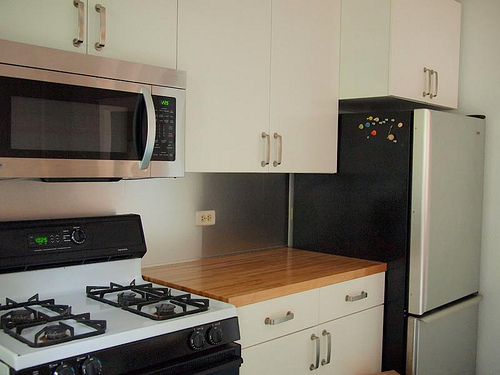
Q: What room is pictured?
A: It is a kitchen.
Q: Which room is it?
A: It is a kitchen.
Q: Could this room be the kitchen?
A: Yes, it is the kitchen.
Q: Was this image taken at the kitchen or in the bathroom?
A: It was taken at the kitchen.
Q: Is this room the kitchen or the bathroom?
A: It is the kitchen.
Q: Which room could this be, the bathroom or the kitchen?
A: It is the kitchen.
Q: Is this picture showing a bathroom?
A: No, the picture is showing a kitchen.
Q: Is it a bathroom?
A: No, it is a kitchen.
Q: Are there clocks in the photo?
A: Yes, there is a clock.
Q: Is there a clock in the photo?
A: Yes, there is a clock.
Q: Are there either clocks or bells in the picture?
A: Yes, there is a clock.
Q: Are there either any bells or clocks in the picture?
A: Yes, there is a clock.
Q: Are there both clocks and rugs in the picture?
A: No, there is a clock but no rugs.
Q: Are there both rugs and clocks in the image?
A: No, there is a clock but no rugs.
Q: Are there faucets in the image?
A: No, there are no faucets.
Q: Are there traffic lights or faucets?
A: No, there are no faucets or traffic lights.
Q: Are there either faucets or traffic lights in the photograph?
A: No, there are no faucets or traffic lights.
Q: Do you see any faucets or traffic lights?
A: No, there are no faucets or traffic lights.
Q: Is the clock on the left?
A: Yes, the clock is on the left of the image.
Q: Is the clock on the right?
A: No, the clock is on the left of the image.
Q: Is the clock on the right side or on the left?
A: The clock is on the left of the image.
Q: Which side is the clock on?
A: The clock is on the left of the image.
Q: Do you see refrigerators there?
A: Yes, there is a refrigerator.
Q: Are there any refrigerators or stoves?
A: Yes, there is a refrigerator.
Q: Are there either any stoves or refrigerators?
A: Yes, there is a refrigerator.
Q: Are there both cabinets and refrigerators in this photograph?
A: Yes, there are both a refrigerator and a cabinet.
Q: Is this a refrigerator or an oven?
A: This is a refrigerator.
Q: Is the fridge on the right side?
A: Yes, the fridge is on the right of the image.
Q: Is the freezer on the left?
A: No, the freezer is on the right of the image.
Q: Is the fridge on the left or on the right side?
A: The fridge is on the right of the image.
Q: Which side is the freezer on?
A: The freezer is on the right of the image.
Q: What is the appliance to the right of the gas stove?
A: The appliance is a refrigerator.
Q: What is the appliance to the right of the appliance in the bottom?
A: The appliance is a refrigerator.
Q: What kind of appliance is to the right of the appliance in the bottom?
A: The appliance is a refrigerator.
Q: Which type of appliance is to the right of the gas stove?
A: The appliance is a refrigerator.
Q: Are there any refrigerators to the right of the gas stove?
A: Yes, there is a refrigerator to the right of the gas stove.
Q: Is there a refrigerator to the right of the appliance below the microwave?
A: Yes, there is a refrigerator to the right of the gas stove.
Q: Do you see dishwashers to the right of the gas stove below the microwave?
A: No, there is a refrigerator to the right of the gas stove.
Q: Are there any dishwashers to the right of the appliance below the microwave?
A: No, there is a refrigerator to the right of the gas stove.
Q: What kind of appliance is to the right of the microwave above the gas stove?
A: The appliance is a refrigerator.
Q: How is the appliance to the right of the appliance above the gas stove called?
A: The appliance is a refrigerator.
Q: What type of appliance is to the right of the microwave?
A: The appliance is a refrigerator.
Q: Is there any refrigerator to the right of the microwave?
A: Yes, there is a refrigerator to the right of the microwave.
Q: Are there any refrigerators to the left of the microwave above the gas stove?
A: No, the refrigerator is to the right of the microwave.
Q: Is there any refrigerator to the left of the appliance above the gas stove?
A: No, the refrigerator is to the right of the microwave.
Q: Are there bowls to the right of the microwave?
A: No, there is a refrigerator to the right of the microwave.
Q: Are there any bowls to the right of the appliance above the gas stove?
A: No, there is a refrigerator to the right of the microwave.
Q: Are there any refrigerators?
A: Yes, there is a refrigerator.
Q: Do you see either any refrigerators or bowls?
A: Yes, there is a refrigerator.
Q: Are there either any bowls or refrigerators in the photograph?
A: Yes, there is a refrigerator.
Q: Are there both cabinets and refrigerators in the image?
A: Yes, there are both a refrigerator and a cabinet.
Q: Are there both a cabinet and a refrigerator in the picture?
A: Yes, there are both a refrigerator and a cabinet.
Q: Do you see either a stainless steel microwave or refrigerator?
A: Yes, there is a stainless steel refrigerator.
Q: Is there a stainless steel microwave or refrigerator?
A: Yes, there is a stainless steel refrigerator.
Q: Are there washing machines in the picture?
A: No, there are no washing machines.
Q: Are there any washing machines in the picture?
A: No, there are no washing machines.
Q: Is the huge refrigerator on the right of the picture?
A: Yes, the fridge is on the right of the image.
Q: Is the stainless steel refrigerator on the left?
A: No, the refrigerator is on the right of the image.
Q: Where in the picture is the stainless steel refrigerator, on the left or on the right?
A: The freezer is on the right of the image.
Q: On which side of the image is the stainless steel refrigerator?
A: The freezer is on the right of the image.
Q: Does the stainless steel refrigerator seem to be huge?
A: Yes, the freezer is huge.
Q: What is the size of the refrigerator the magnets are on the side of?
A: The refrigerator is huge.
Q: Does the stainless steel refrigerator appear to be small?
A: No, the fridge is huge.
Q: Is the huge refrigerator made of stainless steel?
A: Yes, the freezer is made of stainless steel.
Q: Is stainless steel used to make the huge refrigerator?
A: Yes, the freezer is made of stainless steel.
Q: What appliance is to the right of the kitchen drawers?
A: The appliance is a refrigerator.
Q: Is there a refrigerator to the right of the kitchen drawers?
A: Yes, there is a refrigerator to the right of the drawers.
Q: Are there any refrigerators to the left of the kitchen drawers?
A: No, the refrigerator is to the right of the drawers.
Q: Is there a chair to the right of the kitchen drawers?
A: No, there is a refrigerator to the right of the drawers.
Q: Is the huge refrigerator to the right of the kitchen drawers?
A: Yes, the fridge is to the right of the drawers.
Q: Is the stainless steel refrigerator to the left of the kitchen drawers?
A: No, the refrigerator is to the right of the drawers.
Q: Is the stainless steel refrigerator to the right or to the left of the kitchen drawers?
A: The refrigerator is to the right of the drawers.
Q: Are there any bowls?
A: No, there are no bowls.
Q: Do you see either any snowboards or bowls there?
A: No, there are no bowls or snowboards.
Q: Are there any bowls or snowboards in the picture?
A: No, there are no bowls or snowboards.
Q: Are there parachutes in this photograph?
A: No, there are no parachutes.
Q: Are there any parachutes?
A: No, there are no parachutes.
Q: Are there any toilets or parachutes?
A: No, there are no parachutes or toilets.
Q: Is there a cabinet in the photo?
A: Yes, there is a cabinet.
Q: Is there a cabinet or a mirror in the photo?
A: Yes, there is a cabinet.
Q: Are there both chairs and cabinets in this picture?
A: No, there is a cabinet but no chairs.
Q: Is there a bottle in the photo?
A: No, there are no bottles.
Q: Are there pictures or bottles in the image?
A: No, there are no bottles or pictures.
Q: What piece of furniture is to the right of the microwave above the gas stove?
A: The piece of furniture is a cabinet.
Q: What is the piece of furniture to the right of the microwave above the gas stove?
A: The piece of furniture is a cabinet.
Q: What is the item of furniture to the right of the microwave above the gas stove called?
A: The piece of furniture is a cabinet.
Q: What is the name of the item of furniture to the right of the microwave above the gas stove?
A: The piece of furniture is a cabinet.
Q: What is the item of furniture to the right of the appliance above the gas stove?
A: The piece of furniture is a cabinet.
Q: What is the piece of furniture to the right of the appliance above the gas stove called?
A: The piece of furniture is a cabinet.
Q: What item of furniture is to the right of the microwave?
A: The piece of furniture is a cabinet.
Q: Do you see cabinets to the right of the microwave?
A: Yes, there is a cabinet to the right of the microwave.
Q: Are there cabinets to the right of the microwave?
A: Yes, there is a cabinet to the right of the microwave.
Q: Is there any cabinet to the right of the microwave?
A: Yes, there is a cabinet to the right of the microwave.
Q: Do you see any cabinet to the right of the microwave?
A: Yes, there is a cabinet to the right of the microwave.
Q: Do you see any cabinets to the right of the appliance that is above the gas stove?
A: Yes, there is a cabinet to the right of the microwave.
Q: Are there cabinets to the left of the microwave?
A: No, the cabinet is to the right of the microwave.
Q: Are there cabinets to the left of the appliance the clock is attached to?
A: No, the cabinet is to the right of the microwave.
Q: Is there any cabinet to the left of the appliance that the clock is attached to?
A: No, the cabinet is to the right of the microwave.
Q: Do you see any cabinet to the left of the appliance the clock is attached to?
A: No, the cabinet is to the right of the microwave.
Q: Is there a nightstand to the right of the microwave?
A: No, there is a cabinet to the right of the microwave.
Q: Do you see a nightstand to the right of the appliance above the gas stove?
A: No, there is a cabinet to the right of the microwave.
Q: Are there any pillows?
A: No, there are no pillows.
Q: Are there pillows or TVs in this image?
A: No, there are no pillows or tvs.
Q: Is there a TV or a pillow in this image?
A: No, there are no pillows or televisions.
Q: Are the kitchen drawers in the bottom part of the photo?
A: Yes, the drawers are in the bottom of the image.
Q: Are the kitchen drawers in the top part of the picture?
A: No, the drawers are in the bottom of the image.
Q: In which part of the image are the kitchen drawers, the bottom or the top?
A: The drawers are in the bottom of the image.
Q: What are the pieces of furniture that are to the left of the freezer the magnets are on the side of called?
A: The pieces of furniture are drawers.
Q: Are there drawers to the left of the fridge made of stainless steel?
A: Yes, there are drawers to the left of the freezer.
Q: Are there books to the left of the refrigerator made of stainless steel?
A: No, there are drawers to the left of the freezer.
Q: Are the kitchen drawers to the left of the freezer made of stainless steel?
A: Yes, the drawers are to the left of the freezer.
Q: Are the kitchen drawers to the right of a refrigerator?
A: No, the drawers are to the left of a refrigerator.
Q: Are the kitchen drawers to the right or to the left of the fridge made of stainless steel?
A: The drawers are to the left of the freezer.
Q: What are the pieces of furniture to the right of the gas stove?
A: The pieces of furniture are drawers.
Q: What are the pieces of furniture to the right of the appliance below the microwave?
A: The pieces of furniture are drawers.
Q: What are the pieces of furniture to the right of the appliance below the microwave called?
A: The pieces of furniture are drawers.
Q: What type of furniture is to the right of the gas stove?
A: The pieces of furniture are drawers.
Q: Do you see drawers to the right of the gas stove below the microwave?
A: Yes, there are drawers to the right of the gas stove.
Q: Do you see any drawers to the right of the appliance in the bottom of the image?
A: Yes, there are drawers to the right of the gas stove.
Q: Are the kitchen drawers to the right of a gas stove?
A: Yes, the drawers are to the right of a gas stove.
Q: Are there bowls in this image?
A: No, there are no bowls.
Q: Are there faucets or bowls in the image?
A: No, there are no bowls or faucets.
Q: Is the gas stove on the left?
A: Yes, the gas stove is on the left of the image.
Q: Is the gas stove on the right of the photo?
A: No, the gas stove is on the left of the image.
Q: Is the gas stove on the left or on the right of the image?
A: The gas stove is on the left of the image.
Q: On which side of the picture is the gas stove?
A: The gas stove is on the left of the image.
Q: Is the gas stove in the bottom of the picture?
A: Yes, the gas stove is in the bottom of the image.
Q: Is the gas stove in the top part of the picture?
A: No, the gas stove is in the bottom of the image.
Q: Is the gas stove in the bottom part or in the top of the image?
A: The gas stove is in the bottom of the image.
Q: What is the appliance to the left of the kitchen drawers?
A: The appliance is a gas stove.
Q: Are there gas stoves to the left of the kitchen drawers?
A: Yes, there is a gas stove to the left of the drawers.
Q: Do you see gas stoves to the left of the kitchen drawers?
A: Yes, there is a gas stove to the left of the drawers.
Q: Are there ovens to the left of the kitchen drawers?
A: No, there is a gas stove to the left of the drawers.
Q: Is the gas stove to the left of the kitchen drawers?
A: Yes, the gas stove is to the left of the drawers.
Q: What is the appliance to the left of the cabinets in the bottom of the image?
A: The appliance is a gas stove.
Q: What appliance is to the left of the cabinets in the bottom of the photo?
A: The appliance is a gas stove.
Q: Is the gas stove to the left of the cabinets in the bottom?
A: Yes, the gas stove is to the left of the cabinets.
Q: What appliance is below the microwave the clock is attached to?
A: The appliance is a gas stove.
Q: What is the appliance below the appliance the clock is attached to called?
A: The appliance is a gas stove.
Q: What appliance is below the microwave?
A: The appliance is a gas stove.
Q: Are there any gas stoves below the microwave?
A: Yes, there is a gas stove below the microwave.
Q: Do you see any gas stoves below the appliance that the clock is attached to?
A: Yes, there is a gas stove below the microwave.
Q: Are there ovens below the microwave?
A: No, there is a gas stove below the microwave.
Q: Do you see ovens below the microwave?
A: No, there is a gas stove below the microwave.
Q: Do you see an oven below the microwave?
A: No, there is a gas stove below the microwave.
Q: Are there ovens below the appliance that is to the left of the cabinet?
A: No, there is a gas stove below the microwave.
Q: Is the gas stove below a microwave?
A: Yes, the gas stove is below a microwave.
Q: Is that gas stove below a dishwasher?
A: No, the gas stove is below a microwave.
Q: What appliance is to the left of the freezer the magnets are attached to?
A: The appliance is a gas stove.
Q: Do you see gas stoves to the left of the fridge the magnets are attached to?
A: Yes, there is a gas stove to the left of the fridge.